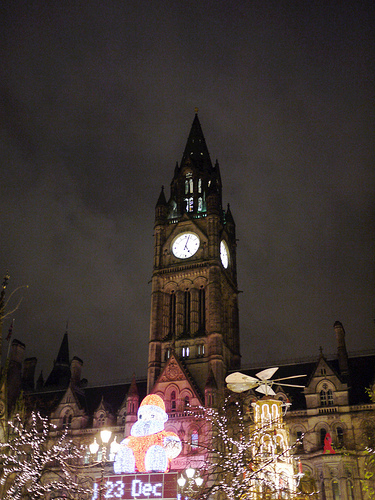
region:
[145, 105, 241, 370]
a tall clock tower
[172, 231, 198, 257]
the clock is illuminated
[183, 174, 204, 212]
windows on top are lit up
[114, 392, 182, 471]
statue of santa claus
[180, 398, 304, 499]
pink lights on tree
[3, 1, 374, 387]
dark clouds in sky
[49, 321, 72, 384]
spire on the building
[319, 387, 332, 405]
windows on the building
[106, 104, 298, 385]
this tower has a clock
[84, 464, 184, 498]
the light says "23 December"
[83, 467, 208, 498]
according to the light it is December 23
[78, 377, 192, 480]
this is Santa Claus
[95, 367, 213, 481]
the lights form Santa Claus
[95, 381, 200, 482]
a Santa made of lights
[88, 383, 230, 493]
Santa Claus made of lights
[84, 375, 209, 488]
red and white lights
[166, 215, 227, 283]
this is a clock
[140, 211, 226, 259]
the hour and minute hands are black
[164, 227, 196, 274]
white clock on tower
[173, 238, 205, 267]
clock has black hands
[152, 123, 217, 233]
clock has dark tower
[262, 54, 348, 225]
dark and grey sky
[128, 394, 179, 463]
Christmas lights in front of tower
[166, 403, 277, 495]
white lights on tree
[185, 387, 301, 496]
trees have bare branches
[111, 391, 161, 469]
red and white lights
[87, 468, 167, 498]
date in front of lights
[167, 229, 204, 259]
clock on a tall tower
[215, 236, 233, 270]
clock on a tall tower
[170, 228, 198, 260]
clock with illuminated face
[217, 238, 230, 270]
clock with illuminated face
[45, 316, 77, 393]
peaked roof on a building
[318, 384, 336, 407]
ornate window on a building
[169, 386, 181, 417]
ornate window on a building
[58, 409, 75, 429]
ornate window on a building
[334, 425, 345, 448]
ornate window on a building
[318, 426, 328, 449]
ornate window on a building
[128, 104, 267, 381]
clock tower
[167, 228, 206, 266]
clock on the side of the tower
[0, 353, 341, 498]
Christmas lights on the building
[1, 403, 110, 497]
Christmas lights on the tree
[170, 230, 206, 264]
white and black clock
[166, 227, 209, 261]
clock indicating it's a little after 5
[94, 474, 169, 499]
the date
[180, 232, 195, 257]
two black clock hands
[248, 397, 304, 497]
lights shining in the night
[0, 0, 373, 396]
faint clouds in the sky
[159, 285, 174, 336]
a window on a building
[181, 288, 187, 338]
a window on a building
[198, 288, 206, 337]
a window on a building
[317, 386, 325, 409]
a window on a building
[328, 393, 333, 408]
a window on a building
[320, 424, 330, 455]
a window on a building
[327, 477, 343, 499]
a window on a building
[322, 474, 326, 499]
a window on a building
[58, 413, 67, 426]
a window on a building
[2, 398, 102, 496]
The lighted tree to the left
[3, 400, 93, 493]
A lighted tree to the left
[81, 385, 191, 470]
The Santa Claus in the middle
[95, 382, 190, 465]
A Santa Claus in the middle